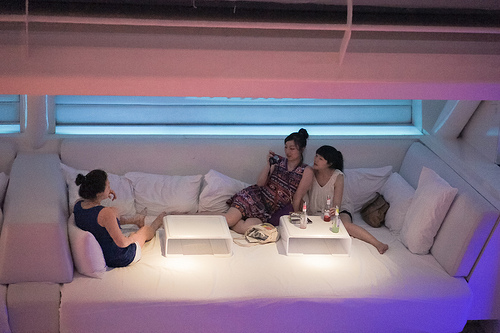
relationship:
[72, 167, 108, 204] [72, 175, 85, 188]
hair in bun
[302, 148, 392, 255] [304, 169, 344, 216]
woman wearing dress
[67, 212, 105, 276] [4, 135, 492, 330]
pillow on couch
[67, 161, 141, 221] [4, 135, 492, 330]
pillow on couch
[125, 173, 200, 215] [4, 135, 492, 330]
pillow on couch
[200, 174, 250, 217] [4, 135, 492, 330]
pillow on couch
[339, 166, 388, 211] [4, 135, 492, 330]
pillow on couch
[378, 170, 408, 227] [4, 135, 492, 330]
pillow on couch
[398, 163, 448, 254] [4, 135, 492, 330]
pillow on couch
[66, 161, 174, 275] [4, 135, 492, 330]
woman sitting on couch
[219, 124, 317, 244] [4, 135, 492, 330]
woman sitting on couch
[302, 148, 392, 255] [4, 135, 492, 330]
woman sitting on couch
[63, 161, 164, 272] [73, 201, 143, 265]
girl wearing dress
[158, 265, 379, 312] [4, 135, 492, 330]
front of couch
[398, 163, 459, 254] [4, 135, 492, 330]
pillow on couch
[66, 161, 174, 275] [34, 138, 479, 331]
woman sitting on couch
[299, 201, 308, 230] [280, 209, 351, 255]
bottle on top of tray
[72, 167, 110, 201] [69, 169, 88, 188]
hair pulled back in bun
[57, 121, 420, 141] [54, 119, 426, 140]
reflection on sill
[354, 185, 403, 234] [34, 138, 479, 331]
purse in corner of couch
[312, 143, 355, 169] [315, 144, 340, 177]
hair on head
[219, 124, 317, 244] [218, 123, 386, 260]
woman next to eachother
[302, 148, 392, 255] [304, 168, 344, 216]
woman with dress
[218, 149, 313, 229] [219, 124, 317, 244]
dress on woman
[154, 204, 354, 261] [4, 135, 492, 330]
trays on couch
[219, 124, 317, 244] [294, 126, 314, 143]
woman has ponytail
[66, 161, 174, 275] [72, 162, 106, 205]
woman has hair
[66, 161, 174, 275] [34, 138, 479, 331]
woman on couch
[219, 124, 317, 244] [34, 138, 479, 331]
woman on couch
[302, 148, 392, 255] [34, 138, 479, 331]
woman on couch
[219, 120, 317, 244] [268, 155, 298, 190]
woman holding camera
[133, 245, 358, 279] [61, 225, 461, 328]
light on sheet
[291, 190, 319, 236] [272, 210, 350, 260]
bottle on table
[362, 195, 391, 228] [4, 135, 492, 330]
purse on couch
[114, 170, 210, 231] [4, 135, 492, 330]
pillow on couch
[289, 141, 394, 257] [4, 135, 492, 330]
girl on couch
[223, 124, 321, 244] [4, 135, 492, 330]
girl on couch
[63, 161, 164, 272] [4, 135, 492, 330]
girl on couch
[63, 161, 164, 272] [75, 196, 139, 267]
girl wearing dress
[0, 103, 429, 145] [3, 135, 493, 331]
windows behind furniture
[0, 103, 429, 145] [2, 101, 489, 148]
windows on wall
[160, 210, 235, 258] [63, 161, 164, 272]
trays are by girl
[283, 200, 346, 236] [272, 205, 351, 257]
bottle on tray